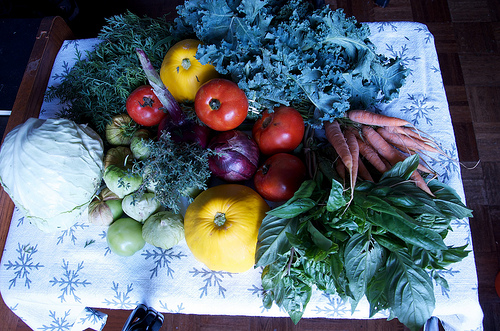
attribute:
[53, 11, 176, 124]
thyme — green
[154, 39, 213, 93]
squash — yellow, little, large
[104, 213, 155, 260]
tomato — green, round, small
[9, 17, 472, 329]
platter — snowflake patterned, leaf motif, designed, blue, white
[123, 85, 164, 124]
tomato — red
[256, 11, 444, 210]
carrots — orange, clustered, grouped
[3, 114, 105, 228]
cabbage — green, light green, fresh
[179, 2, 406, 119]
kale — large, leafy, green, dark green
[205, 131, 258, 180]
onion — large, red, purple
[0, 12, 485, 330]
table — brown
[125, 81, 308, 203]
tomatoes — red, grouped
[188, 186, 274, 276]
squash — large, yellow